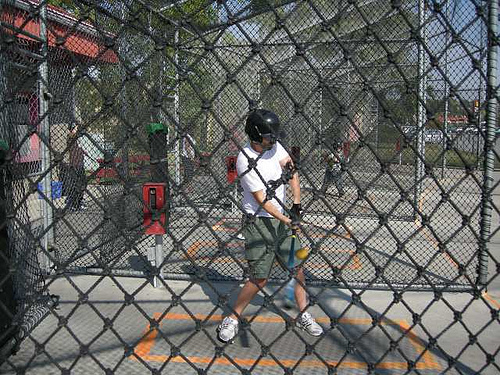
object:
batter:
[217, 108, 326, 341]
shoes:
[218, 310, 324, 342]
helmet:
[244, 109, 280, 146]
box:
[142, 181, 169, 235]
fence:
[1, 0, 499, 374]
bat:
[278, 224, 302, 267]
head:
[244, 110, 281, 150]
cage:
[0, 0, 498, 372]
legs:
[232, 242, 307, 317]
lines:
[127, 311, 441, 372]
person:
[64, 123, 89, 210]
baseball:
[295, 247, 308, 260]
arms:
[236, 155, 276, 209]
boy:
[217, 109, 326, 342]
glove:
[289, 203, 305, 225]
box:
[127, 311, 439, 370]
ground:
[5, 159, 498, 373]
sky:
[217, 5, 499, 111]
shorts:
[240, 214, 304, 278]